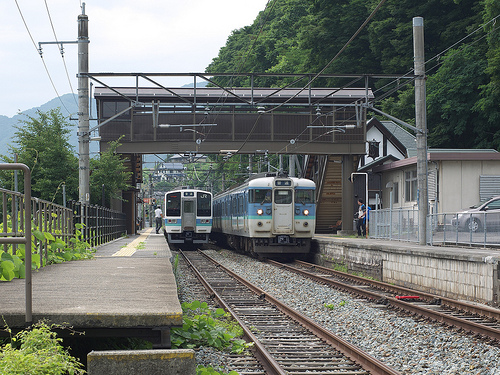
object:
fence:
[0, 198, 129, 278]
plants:
[32, 227, 49, 244]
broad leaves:
[33, 226, 48, 242]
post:
[349, 170, 369, 238]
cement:
[85, 346, 195, 373]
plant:
[1, 318, 83, 374]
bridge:
[93, 88, 373, 152]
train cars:
[219, 175, 319, 263]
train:
[212, 175, 318, 262]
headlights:
[255, 207, 263, 216]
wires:
[43, 0, 79, 119]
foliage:
[204, 0, 498, 148]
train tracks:
[180, 246, 469, 374]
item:
[394, 293, 418, 301]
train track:
[175, 244, 412, 374]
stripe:
[107, 223, 149, 256]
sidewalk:
[0, 210, 180, 339]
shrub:
[170, 297, 255, 359]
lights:
[299, 207, 310, 216]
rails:
[0, 188, 74, 275]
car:
[450, 195, 498, 233]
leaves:
[0, 262, 15, 283]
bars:
[1, 163, 33, 322]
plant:
[168, 299, 256, 350]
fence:
[363, 204, 499, 246]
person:
[152, 207, 160, 233]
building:
[359, 111, 429, 234]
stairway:
[318, 124, 359, 224]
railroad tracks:
[248, 256, 499, 345]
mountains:
[0, 88, 172, 139]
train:
[160, 188, 213, 248]